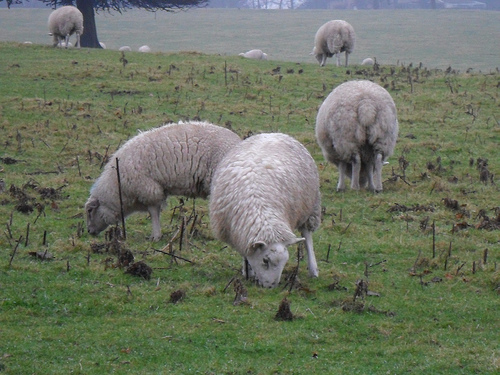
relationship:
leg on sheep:
[138, 184, 166, 243] [82, 120, 244, 244]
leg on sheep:
[300, 225, 326, 277] [208, 131, 324, 289]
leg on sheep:
[349, 155, 363, 189] [315, 78, 401, 192]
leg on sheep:
[335, 163, 346, 193] [315, 78, 401, 192]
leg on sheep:
[373, 153, 387, 192] [315, 78, 401, 192]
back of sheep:
[328, 87, 402, 187] [315, 78, 401, 192]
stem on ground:
[115, 157, 131, 241] [6, 8, 499, 373]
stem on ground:
[178, 217, 188, 248] [6, 8, 499, 373]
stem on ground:
[42, 229, 47, 243] [6, 8, 499, 373]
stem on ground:
[24, 223, 34, 246] [6, 8, 499, 373]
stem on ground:
[431, 222, 438, 257] [6, 8, 499, 373]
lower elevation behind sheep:
[0, 5, 499, 71] [312, 19, 354, 67]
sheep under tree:
[47, 5, 84, 48] [0, 0, 209, 53]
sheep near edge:
[312, 19, 354, 67] [1, 36, 499, 80]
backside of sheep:
[328, 20, 353, 65] [312, 19, 354, 67]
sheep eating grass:
[47, 5, 84, 48] [2, 40, 497, 374]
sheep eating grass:
[312, 19, 354, 67] [2, 40, 497, 374]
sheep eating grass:
[315, 78, 401, 192] [2, 40, 497, 374]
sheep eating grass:
[208, 131, 324, 289] [2, 40, 497, 374]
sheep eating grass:
[82, 120, 244, 244] [2, 40, 497, 374]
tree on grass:
[0, 0, 209, 53] [2, 40, 497, 374]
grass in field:
[2, 40, 497, 374] [6, 8, 499, 373]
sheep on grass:
[47, 5, 84, 48] [2, 40, 497, 374]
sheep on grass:
[312, 19, 354, 67] [2, 40, 497, 374]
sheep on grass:
[315, 78, 401, 192] [2, 40, 497, 374]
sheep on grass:
[208, 131, 324, 289] [2, 40, 497, 374]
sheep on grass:
[82, 120, 244, 244] [2, 40, 497, 374]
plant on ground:
[275, 299, 290, 318] [6, 8, 499, 373]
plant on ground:
[16, 203, 46, 213] [6, 8, 499, 373]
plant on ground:
[124, 260, 153, 278] [6, 8, 499, 373]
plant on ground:
[443, 197, 459, 209] [6, 8, 499, 373]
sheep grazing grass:
[82, 120, 244, 244] [2, 40, 497, 374]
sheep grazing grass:
[208, 131, 324, 289] [2, 40, 497, 374]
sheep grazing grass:
[315, 78, 401, 192] [2, 40, 497, 374]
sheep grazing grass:
[312, 19, 354, 67] [2, 40, 497, 374]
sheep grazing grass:
[47, 5, 84, 48] [2, 40, 497, 374]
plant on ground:
[348, 279, 367, 303] [6, 8, 499, 373]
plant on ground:
[474, 156, 493, 182] [6, 8, 499, 373]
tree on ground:
[0, 0, 209, 53] [6, 8, 499, 373]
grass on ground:
[2, 40, 497, 374] [6, 8, 499, 373]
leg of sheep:
[334, 50, 340, 67] [312, 19, 354, 67]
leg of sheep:
[344, 51, 349, 64] [312, 19, 354, 67]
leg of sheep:
[75, 32, 83, 48] [47, 5, 84, 48]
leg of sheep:
[63, 33, 71, 49] [47, 5, 84, 48]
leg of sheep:
[373, 153, 387, 192] [315, 78, 401, 192]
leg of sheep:
[335, 163, 346, 193] [315, 78, 401, 192]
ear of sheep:
[251, 240, 267, 251] [208, 131, 324, 289]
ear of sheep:
[285, 237, 305, 245] [208, 131, 324, 289]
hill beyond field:
[298, 2, 499, 10] [5, 46, 493, 372]